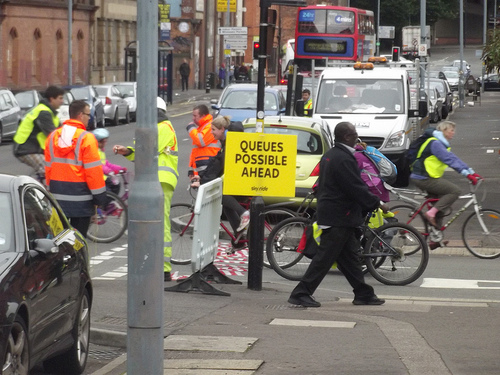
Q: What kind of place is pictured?
A: It is a street.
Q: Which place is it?
A: It is a street.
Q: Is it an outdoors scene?
A: Yes, it is outdoors.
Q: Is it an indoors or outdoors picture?
A: It is outdoors.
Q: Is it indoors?
A: No, it is outdoors.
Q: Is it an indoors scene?
A: No, it is outdoors.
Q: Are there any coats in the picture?
A: Yes, there is a coat.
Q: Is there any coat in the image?
A: Yes, there is a coat.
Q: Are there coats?
A: Yes, there is a coat.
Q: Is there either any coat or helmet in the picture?
A: Yes, there is a coat.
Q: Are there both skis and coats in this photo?
A: No, there is a coat but no skis.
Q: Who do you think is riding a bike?
A: The man is riding a bike.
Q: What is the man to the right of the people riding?
A: The man is riding a bike.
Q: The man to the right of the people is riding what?
A: The man is riding a bike.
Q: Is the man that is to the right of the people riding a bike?
A: Yes, the man is riding a bike.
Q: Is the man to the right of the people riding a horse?
A: No, the man is riding a bike.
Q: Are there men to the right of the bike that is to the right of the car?
A: Yes, there is a man to the right of the bike.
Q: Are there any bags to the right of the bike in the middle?
A: No, there is a man to the right of the bike.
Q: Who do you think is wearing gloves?
A: The man is wearing gloves.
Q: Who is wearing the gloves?
A: The man is wearing gloves.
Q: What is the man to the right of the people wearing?
A: The man is wearing gloves.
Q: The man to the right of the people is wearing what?
A: The man is wearing gloves.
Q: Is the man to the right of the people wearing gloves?
A: Yes, the man is wearing gloves.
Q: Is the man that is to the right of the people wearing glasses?
A: No, the man is wearing gloves.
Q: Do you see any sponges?
A: No, there are no sponges.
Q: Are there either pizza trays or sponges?
A: No, there are no sponges or pizza trays.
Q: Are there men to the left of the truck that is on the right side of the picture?
A: Yes, there is a man to the left of the truck.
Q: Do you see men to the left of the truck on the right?
A: Yes, there is a man to the left of the truck.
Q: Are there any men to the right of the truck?
A: No, the man is to the left of the truck.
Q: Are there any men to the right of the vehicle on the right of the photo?
A: No, the man is to the left of the truck.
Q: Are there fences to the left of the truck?
A: No, there is a man to the left of the truck.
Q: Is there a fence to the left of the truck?
A: No, there is a man to the left of the truck.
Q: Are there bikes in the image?
A: Yes, there is a bike.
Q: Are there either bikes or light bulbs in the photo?
A: Yes, there is a bike.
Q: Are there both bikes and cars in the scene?
A: Yes, there are both a bike and a car.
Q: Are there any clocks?
A: No, there are no clocks.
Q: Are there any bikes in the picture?
A: Yes, there is a bike.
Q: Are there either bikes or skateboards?
A: Yes, there is a bike.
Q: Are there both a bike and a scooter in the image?
A: No, there is a bike but no scooters.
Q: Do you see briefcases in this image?
A: No, there are no briefcases.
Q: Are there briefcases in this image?
A: No, there are no briefcases.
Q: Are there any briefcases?
A: No, there are no briefcases.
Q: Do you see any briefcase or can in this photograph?
A: No, there are no briefcases or cans.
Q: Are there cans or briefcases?
A: No, there are no briefcases or cans.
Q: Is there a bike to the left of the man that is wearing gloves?
A: Yes, there is a bike to the left of the man.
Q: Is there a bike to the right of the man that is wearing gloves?
A: No, the bike is to the left of the man.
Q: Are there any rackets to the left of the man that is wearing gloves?
A: No, there is a bike to the left of the man.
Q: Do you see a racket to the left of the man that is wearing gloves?
A: No, there is a bike to the left of the man.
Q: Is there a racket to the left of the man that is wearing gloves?
A: No, there is a bike to the left of the man.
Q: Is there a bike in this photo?
A: Yes, there is a bike.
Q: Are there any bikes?
A: Yes, there is a bike.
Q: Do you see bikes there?
A: Yes, there is a bike.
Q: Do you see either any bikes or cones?
A: Yes, there is a bike.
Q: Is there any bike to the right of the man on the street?
A: Yes, there is a bike to the right of the man.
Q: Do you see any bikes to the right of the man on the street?
A: Yes, there is a bike to the right of the man.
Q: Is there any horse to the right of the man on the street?
A: No, there is a bike to the right of the man.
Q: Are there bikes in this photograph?
A: Yes, there is a bike.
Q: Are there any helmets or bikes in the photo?
A: Yes, there is a bike.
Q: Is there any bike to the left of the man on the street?
A: Yes, there is a bike to the left of the man.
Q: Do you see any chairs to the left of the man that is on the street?
A: No, there is a bike to the left of the man.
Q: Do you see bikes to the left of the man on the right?
A: Yes, there is a bike to the left of the man.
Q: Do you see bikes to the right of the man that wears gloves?
A: No, the bike is to the left of the man.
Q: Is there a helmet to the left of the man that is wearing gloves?
A: No, there is a bike to the left of the man.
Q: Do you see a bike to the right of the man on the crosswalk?
A: Yes, there is a bike to the right of the man.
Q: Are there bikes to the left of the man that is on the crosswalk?
A: No, the bike is to the right of the man.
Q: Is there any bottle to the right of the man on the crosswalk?
A: No, there is a bike to the right of the man.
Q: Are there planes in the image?
A: No, there are no planes.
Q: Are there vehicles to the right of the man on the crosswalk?
A: Yes, there is a vehicle to the right of the man.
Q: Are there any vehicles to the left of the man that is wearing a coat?
A: No, the vehicle is to the right of the man.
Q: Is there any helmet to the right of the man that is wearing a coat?
A: No, there is a vehicle to the right of the man.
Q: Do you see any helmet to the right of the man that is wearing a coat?
A: No, there is a vehicle to the right of the man.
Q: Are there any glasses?
A: No, there are no glasses.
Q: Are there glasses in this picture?
A: No, there are no glasses.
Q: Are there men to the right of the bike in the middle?
A: Yes, there is a man to the right of the bike.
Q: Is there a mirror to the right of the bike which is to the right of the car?
A: No, there is a man to the right of the bike.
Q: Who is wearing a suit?
A: The man is wearing a suit.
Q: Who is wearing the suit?
A: The man is wearing a suit.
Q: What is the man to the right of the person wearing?
A: The man is wearing a suit.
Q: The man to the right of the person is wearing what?
A: The man is wearing a suit.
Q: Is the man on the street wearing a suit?
A: Yes, the man is wearing a suit.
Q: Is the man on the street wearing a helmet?
A: No, the man is wearing a suit.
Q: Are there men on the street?
A: Yes, there is a man on the street.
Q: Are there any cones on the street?
A: No, there is a man on the street.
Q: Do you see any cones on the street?
A: No, there is a man on the street.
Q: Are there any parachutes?
A: No, there are no parachutes.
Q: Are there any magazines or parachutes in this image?
A: No, there are no parachutes or magazines.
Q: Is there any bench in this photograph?
A: No, there are no benches.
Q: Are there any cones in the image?
A: No, there are no cones.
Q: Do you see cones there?
A: No, there are no cones.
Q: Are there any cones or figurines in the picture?
A: No, there are no cones or figurines.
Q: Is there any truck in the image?
A: Yes, there is a truck.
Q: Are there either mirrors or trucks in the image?
A: Yes, there is a truck.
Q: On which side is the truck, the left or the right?
A: The truck is on the right of the image.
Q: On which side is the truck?
A: The truck is on the right of the image.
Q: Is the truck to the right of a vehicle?
A: Yes, the truck is to the right of a vehicle.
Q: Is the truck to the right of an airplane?
A: No, the truck is to the right of a vehicle.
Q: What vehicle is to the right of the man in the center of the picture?
A: The vehicle is a truck.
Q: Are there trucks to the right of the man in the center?
A: Yes, there is a truck to the right of the man.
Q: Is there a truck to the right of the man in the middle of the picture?
A: Yes, there is a truck to the right of the man.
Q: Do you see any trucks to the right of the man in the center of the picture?
A: Yes, there is a truck to the right of the man.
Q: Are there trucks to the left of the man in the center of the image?
A: No, the truck is to the right of the man.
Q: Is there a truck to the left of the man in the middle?
A: No, the truck is to the right of the man.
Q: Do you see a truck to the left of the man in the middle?
A: No, the truck is to the right of the man.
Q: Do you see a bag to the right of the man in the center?
A: No, there is a truck to the right of the man.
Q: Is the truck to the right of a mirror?
A: No, the truck is to the right of a man.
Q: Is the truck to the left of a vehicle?
A: No, the truck is to the right of a vehicle.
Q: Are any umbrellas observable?
A: No, there are no umbrellas.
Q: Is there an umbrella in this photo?
A: No, there are no umbrellas.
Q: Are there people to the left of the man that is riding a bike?
A: Yes, there are people to the left of the man.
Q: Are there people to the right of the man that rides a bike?
A: No, the people are to the left of the man.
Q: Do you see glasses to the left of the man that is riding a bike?
A: No, there are people to the left of the man.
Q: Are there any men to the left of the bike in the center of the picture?
A: Yes, there is a man to the left of the bike.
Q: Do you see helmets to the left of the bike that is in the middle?
A: No, there is a man to the left of the bike.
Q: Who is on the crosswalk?
A: The man is on the crosswalk.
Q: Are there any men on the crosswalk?
A: Yes, there is a man on the crosswalk.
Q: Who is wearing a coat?
A: The man is wearing a coat.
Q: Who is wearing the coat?
A: The man is wearing a coat.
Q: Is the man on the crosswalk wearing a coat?
A: Yes, the man is wearing a coat.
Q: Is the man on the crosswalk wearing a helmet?
A: No, the man is wearing a coat.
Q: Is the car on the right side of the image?
A: No, the car is on the left of the image.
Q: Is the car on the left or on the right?
A: The car is on the left of the image.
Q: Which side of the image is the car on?
A: The car is on the left of the image.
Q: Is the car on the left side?
A: Yes, the car is on the left of the image.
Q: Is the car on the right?
A: No, the car is on the left of the image.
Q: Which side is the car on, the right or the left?
A: The car is on the left of the image.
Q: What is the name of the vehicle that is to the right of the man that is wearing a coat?
A: The vehicle is a car.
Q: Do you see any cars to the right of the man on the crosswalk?
A: Yes, there is a car to the right of the man.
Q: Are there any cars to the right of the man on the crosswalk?
A: Yes, there is a car to the right of the man.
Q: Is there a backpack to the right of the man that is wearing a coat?
A: No, there is a car to the right of the man.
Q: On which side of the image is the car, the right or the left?
A: The car is on the left of the image.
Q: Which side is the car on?
A: The car is on the left of the image.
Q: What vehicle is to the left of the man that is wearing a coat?
A: The vehicle is a car.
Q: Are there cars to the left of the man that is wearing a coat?
A: Yes, there is a car to the left of the man.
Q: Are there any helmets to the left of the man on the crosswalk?
A: No, there is a car to the left of the man.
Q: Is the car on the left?
A: Yes, the car is on the left of the image.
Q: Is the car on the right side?
A: No, the car is on the left of the image.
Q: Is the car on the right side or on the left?
A: The car is on the left of the image.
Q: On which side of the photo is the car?
A: The car is on the left of the image.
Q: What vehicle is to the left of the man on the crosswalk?
A: The vehicle is a car.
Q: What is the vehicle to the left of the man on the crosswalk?
A: The vehicle is a car.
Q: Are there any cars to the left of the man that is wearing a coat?
A: Yes, there is a car to the left of the man.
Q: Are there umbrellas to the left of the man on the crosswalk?
A: No, there is a car to the left of the man.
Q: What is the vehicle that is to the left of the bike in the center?
A: The vehicle is a car.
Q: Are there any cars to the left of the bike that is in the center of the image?
A: Yes, there is a car to the left of the bike.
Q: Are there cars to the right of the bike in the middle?
A: No, the car is to the left of the bike.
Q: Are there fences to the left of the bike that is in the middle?
A: No, there is a car to the left of the bike.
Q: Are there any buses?
A: Yes, there is a bus.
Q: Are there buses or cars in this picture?
A: Yes, there is a bus.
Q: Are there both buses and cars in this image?
A: Yes, there are both a bus and a car.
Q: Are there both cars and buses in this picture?
A: Yes, there are both a bus and a car.